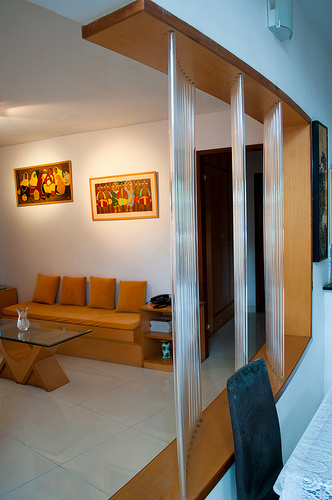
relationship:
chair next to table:
[229, 358, 282, 500] [273, 384, 330, 499]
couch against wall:
[5, 273, 157, 364] [0, 107, 264, 304]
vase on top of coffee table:
[15, 305, 30, 332] [3, 317, 91, 392]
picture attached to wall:
[90, 172, 159, 221] [0, 107, 264, 304]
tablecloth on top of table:
[275, 379, 331, 498] [273, 384, 330, 499]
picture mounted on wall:
[312, 119, 332, 262] [153, 2, 331, 341]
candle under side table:
[161, 340, 170, 360] [139, 301, 206, 373]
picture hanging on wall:
[90, 172, 159, 221] [0, 107, 264, 304]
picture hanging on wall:
[12, 159, 75, 209] [0, 107, 264, 304]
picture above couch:
[90, 172, 159, 221] [5, 273, 157, 364]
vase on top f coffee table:
[15, 305, 30, 332] [3, 317, 91, 392]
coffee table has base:
[3, 317, 91, 392] [2, 338, 68, 391]